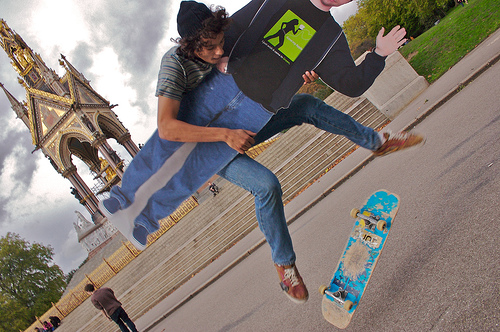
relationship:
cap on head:
[172, 0, 221, 29] [172, 2, 236, 76]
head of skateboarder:
[172, 2, 236, 76] [150, 2, 426, 308]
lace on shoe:
[284, 266, 304, 288] [275, 256, 307, 304]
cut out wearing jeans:
[95, 0, 411, 253] [102, 70, 270, 225]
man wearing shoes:
[153, 2, 428, 302] [373, 130, 421, 152]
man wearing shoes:
[153, 2, 428, 302] [274, 257, 313, 303]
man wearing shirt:
[153, 2, 428, 302] [153, 44, 218, 99]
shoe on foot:
[267, 261, 307, 305] [274, 251, 307, 302]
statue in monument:
[94, 153, 117, 183] [2, 18, 142, 250]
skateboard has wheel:
[314, 185, 400, 330] [347, 206, 365, 224]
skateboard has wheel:
[314, 185, 400, 330] [373, 217, 390, 230]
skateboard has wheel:
[314, 185, 400, 330] [340, 297, 353, 313]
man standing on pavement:
[84, 275, 130, 325] [88, 71, 483, 323]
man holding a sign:
[153, 2, 428, 302] [95, 5, 409, 251]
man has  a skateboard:
[153, 0, 428, 302] [317, 183, 405, 323]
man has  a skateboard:
[153, 0, 428, 302] [311, 186, 408, 317]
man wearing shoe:
[153, 0, 428, 302] [272, 257, 311, 302]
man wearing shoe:
[153, 0, 428, 302] [370, 125, 426, 155]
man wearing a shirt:
[84, 280, 139, 332] [89, 285, 120, 312]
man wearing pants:
[84, 280, 139, 332] [113, 311, 135, 326]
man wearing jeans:
[153, 0, 428, 302] [226, 86, 378, 262]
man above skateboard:
[153, 2, 428, 302] [314, 185, 400, 330]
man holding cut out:
[153, 2, 428, 302] [95, 6, 408, 247]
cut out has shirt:
[95, 6, 408, 247] [215, 6, 385, 117]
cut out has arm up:
[95, 6, 408, 247] [320, 15, 412, 96]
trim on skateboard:
[354, 223, 379, 245] [317, 183, 405, 323]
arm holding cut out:
[157, 50, 258, 156] [95, 0, 411, 253]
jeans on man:
[164, 111, 379, 297] [153, 0, 428, 302]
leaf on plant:
[414, 18, 472, 108] [355, 10, 479, 121]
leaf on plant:
[393, 30, 421, 76] [362, 1, 467, 114]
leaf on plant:
[23, 249, 39, 279] [2, 215, 78, 303]